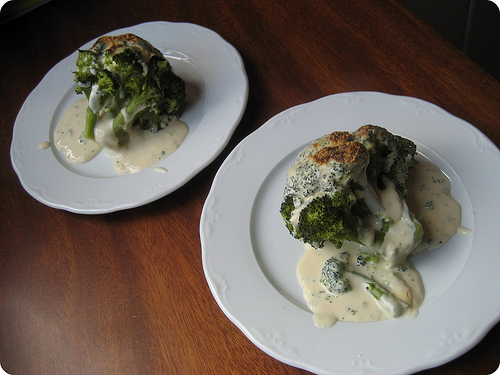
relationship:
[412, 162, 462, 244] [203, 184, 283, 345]
cream on plate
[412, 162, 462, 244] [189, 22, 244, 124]
cream on plate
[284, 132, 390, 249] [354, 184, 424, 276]
broccoli has stem